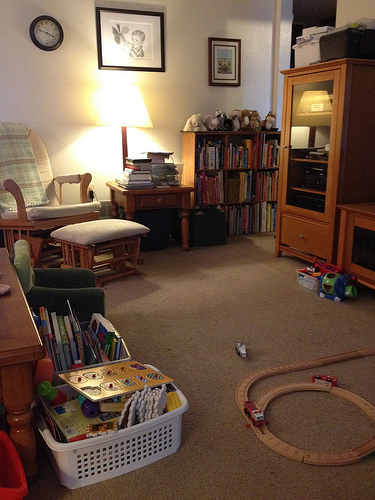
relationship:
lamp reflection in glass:
[294, 90, 332, 150] [283, 81, 333, 215]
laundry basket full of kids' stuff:
[31, 363, 190, 492] [36, 361, 183, 445]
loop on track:
[256, 381, 372, 468] [234, 343, 373, 468]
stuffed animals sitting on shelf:
[183, 109, 278, 132] [179, 131, 282, 242]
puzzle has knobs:
[59, 360, 175, 403] [78, 363, 158, 388]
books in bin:
[30, 298, 122, 373] [52, 317, 132, 385]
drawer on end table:
[141, 194, 178, 209] [106, 179, 195, 253]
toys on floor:
[234, 255, 373, 470] [22, 231, 375, 500]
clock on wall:
[30, 15, 65, 53] [1, 0, 276, 206]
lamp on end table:
[85, 78, 156, 173] [106, 179, 195, 253]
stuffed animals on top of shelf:
[183, 109, 278, 132] [179, 131, 282, 242]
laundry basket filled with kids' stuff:
[31, 363, 190, 492] [36, 361, 183, 445]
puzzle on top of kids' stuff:
[59, 360, 175, 403] [36, 361, 183, 445]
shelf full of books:
[179, 131, 282, 242] [193, 135, 279, 234]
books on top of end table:
[115, 148, 179, 192] [106, 179, 195, 253]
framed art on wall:
[96, 8, 167, 74] [1, 0, 276, 206]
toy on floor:
[235, 341, 249, 359] [22, 231, 375, 500]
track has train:
[234, 343, 373, 468] [243, 398, 265, 428]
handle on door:
[282, 144, 287, 151] [280, 69, 341, 227]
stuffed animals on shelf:
[183, 109, 278, 132] [179, 131, 282, 242]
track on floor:
[234, 343, 373, 468] [22, 231, 375, 500]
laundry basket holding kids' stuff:
[31, 363, 190, 492] [36, 361, 183, 445]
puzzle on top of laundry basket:
[59, 360, 175, 403] [31, 363, 190, 492]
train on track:
[243, 398, 265, 428] [234, 343, 373, 468]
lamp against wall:
[85, 78, 156, 173] [1, 0, 276, 206]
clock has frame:
[30, 15, 65, 53] [28, 16, 64, 52]